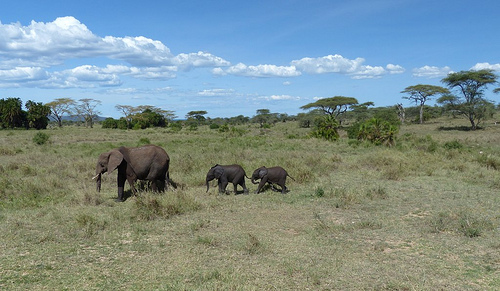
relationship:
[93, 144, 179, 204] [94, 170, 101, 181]
elephant has tusk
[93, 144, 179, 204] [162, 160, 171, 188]
elephant has tail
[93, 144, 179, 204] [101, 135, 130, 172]
elephant has ear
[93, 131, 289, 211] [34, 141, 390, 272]
elephants are in field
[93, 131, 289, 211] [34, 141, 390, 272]
elephants walking in field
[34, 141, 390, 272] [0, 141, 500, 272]
field has field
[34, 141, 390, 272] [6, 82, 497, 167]
field has trees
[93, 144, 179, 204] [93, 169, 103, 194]
elephant has trunk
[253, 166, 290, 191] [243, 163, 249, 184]
elephant holds tail